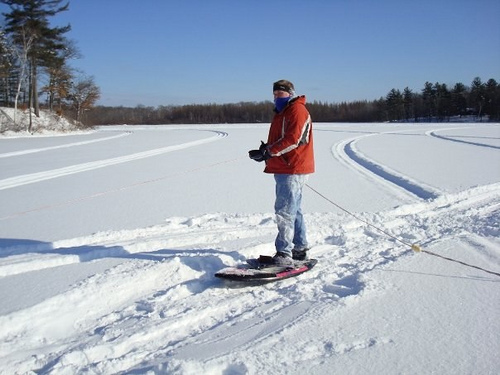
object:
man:
[249, 79, 316, 270]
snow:
[0, 107, 500, 373]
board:
[213, 253, 320, 284]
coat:
[262, 94, 317, 175]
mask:
[272, 95, 291, 116]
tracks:
[331, 129, 442, 200]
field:
[0, 122, 500, 374]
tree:
[383, 89, 409, 124]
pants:
[274, 171, 309, 252]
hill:
[0, 103, 84, 132]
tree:
[0, 0, 100, 126]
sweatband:
[272, 84, 294, 91]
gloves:
[249, 143, 271, 162]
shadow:
[0, 238, 258, 277]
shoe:
[269, 249, 298, 267]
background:
[0, 1, 500, 126]